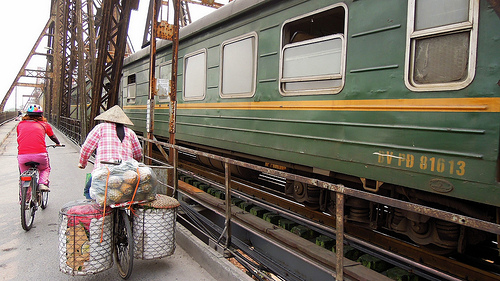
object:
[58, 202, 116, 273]
basket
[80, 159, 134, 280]
bicycle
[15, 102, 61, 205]
woman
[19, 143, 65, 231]
bike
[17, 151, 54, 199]
pants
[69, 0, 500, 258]
passenger train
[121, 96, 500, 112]
stripe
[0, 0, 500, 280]
scene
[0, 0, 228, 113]
sky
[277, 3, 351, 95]
window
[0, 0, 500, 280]
bridge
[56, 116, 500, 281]
fence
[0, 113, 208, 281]
pavement